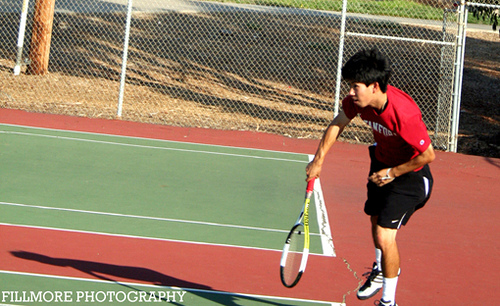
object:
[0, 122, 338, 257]
square patch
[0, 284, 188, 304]
lettering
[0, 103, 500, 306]
tennis court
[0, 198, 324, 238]
white lines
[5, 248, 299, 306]
shadow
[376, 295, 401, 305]
shoe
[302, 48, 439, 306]
he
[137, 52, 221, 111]
chain link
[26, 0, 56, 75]
pole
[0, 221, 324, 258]
white lines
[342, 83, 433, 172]
t shirt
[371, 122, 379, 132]
letters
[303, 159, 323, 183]
hand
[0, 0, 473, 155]
fence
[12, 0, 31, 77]
pole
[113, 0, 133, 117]
pole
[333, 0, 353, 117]
pole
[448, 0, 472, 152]
pole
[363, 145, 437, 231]
shorts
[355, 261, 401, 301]
shoe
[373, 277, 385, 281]
stripes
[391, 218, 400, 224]
logo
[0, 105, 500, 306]
red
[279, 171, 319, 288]
racquet